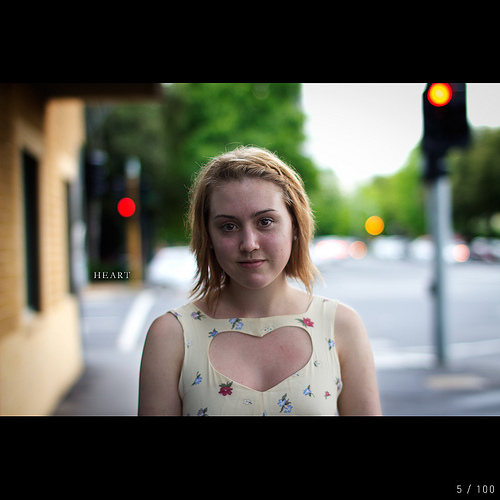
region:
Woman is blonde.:
[127, 133, 385, 420]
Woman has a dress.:
[123, 136, 386, 418]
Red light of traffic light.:
[93, 178, 143, 263]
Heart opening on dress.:
[200, 321, 320, 396]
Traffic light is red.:
[412, 85, 476, 190]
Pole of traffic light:
[423, 173, 455, 369]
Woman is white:
[119, 141, 394, 418]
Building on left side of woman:
[0, 93, 97, 413]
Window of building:
[14, 130, 49, 320]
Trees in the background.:
[296, 99, 422, 241]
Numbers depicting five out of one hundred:
[449, 481, 497, 498]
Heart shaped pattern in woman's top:
[198, 310, 328, 396]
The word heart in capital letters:
[86, 264, 134, 286]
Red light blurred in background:
[108, 182, 138, 234]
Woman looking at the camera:
[186, 164, 303, 290]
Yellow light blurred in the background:
[359, 212, 389, 239]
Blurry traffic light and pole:
[406, 83, 471, 368]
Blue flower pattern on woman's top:
[273, 392, 294, 414]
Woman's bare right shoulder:
[141, 312, 187, 379]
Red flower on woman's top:
[213, 379, 233, 396]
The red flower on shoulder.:
[293, 305, 319, 332]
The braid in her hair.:
[223, 152, 298, 180]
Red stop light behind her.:
[97, 202, 149, 217]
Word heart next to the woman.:
[67, 261, 145, 286]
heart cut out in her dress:
[197, 317, 322, 392]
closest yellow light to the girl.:
[410, 81, 471, 103]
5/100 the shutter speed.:
[447, 477, 497, 497]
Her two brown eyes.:
[207, 211, 289, 236]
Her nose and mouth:
[227, 243, 277, 273]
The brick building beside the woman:
[9, 123, 74, 387]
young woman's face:
[189, 146, 322, 295]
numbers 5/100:
[456, 482, 496, 494]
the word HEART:
[92, 270, 132, 280]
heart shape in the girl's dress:
[208, 326, 314, 390]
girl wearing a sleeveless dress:
[167, 140, 342, 410]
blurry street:
[376, 250, 493, 403]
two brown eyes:
[223, 217, 274, 230]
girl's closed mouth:
[237, 256, 267, 264]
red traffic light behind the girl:
[418, 81, 475, 167]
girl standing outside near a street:
[134, 139, 380, 413]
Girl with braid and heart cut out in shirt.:
[138, 143, 384, 413]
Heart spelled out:
[53, 212, 160, 319]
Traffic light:
[347, 83, 498, 156]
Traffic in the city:
[327, 213, 498, 302]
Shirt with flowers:
[141, 277, 370, 415]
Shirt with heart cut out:
[133, 282, 380, 415]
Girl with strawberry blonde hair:
[168, 140, 328, 306]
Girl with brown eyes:
[166, 144, 323, 310]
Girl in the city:
[66, 137, 496, 367]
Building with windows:
[3, 85, 177, 412]